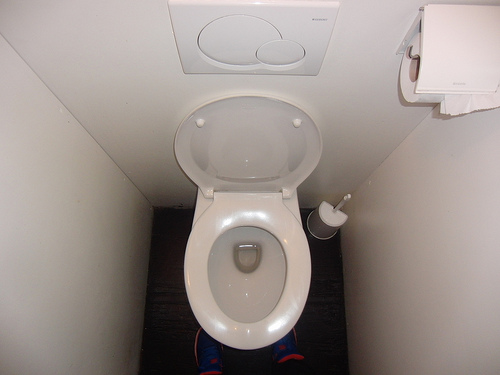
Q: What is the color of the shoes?
A: Blue.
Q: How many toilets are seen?
A: One.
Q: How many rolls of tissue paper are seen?
A: One.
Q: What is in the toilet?
A: Water.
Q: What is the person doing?
A: Using the toilet.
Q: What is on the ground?
A: A toilet.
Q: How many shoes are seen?
A: Two.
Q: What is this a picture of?
A: Bathroom.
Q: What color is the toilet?
A: White.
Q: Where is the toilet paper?
A: On the wall.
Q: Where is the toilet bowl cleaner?
A: In the right corner.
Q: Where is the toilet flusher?
A: Behind the toilet.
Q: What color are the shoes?
A: Blue and orange.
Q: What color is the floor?
A: Black.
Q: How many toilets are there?
A: 1.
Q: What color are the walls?
A: White.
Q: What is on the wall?
A: Toilet paper.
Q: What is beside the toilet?
A: Brush.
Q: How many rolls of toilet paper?
A: One.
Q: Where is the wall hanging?
A: Above the toilet.